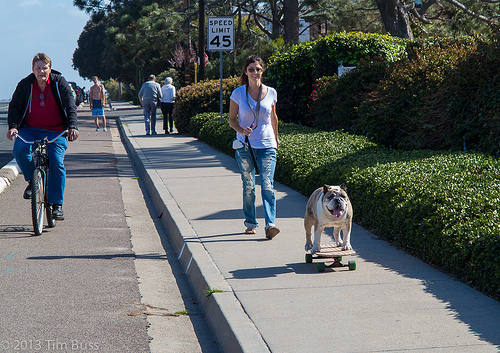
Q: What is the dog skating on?
A: Skateboard.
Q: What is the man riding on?
A: Bicycle.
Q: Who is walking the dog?
A: The woman.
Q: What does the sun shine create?
A: Shadows.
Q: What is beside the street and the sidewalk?
A: The curb.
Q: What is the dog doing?
A: Riding a skateboard.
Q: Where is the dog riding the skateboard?
A: On the sidewalk.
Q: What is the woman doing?
A: Walking on the sidewalk.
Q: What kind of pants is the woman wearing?
A: Blue jeans.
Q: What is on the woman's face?
A: Sunglasses.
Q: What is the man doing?
A: Riding a bike.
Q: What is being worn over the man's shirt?
A: A black jacket.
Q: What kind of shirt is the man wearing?
A: A red collared shirt.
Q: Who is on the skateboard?
A: Dog.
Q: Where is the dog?
A: On the skateboard.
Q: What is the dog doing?
A: Riding a skateboard.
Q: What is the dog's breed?
A: Bulldog.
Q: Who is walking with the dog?
A: The woman.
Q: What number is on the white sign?
A: 45.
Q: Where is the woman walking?
A: On the sidewalk.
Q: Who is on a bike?
A: The man with the red shirt.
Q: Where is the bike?
A: On the roadside.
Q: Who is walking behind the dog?
A: Lady.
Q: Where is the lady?
A: Sidewalk.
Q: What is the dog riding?
A: Skateboard.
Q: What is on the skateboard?
A: Dog.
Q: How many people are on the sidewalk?
A: Three.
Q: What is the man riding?
A: Bicycle.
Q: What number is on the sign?
A: Forty-five.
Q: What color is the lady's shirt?
A: White.